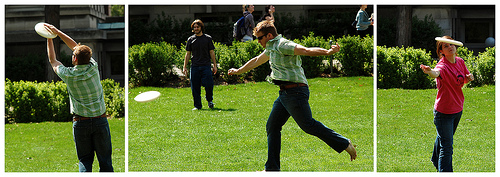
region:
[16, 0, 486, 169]
A collage of three pictures.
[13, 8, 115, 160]
One man in left picture.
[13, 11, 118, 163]
Man in left picture catching frisbee.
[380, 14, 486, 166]
Woman in right picture catching frisbee.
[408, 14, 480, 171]
Woman catching a white frisbee.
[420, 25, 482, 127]
Woman wearing a pink shirt.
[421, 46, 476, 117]
A pink short sleeve shirt.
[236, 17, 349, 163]
Man in middle picture wearing green and white shirt.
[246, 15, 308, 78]
Man in middle picture wearing sunglasses.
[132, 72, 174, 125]
White frisbee in middle picture.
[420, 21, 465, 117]
A girl in a red shirt tossing a frisbie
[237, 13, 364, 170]
A barefooted man in jeans and a green shirt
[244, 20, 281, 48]
The man is wearing sunglasses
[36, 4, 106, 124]
Man in green and white shirt catching a frisbie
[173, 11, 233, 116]
A man wearing a blue shirt and denim jeans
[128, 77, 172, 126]
A frisbie in flight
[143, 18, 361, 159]
Playing frisbie on grass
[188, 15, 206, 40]
A man with long brown hair and facial hair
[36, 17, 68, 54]
Catching a frisbie with two hands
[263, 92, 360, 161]
A bare foot and jeans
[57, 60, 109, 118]
the man is wearing a short sleeve shirt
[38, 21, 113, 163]
the man is holding a frisbee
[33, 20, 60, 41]
the frisbee is made of plastic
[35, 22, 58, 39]
the frisbee is white in color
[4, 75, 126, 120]
the bushes is behind the man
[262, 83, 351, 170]
the man is wearing long pants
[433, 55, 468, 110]
the woman is wearing a short sleeve shirt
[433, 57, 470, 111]
the shirt is red in color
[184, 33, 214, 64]
the man is wearing a short sleeve shirt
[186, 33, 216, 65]
the shirt is black in color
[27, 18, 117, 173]
A man catching a frisbee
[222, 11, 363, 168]
A man jumping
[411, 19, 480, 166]
A woman tossing a frisbee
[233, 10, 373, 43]
People in the background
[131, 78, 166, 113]
A yellow frisbee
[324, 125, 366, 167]
A bare foot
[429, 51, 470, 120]
A pink tee shirt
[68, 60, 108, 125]
A green plaid shirt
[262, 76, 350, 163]
A pair of blue jeans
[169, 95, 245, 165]
A large green lawn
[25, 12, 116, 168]
Frisbee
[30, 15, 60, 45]
Frisbee is white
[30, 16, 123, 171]
man holding a Frisbee with both hands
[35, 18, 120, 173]
man wears a green squared shirt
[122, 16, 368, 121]
man throwing a Frisbee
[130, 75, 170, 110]
Frisbee is in the air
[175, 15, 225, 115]
man stands on green grass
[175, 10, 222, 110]
man wears dark clothes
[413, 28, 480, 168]
woman throwing a Frisbee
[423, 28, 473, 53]
a Frisbee in front a woman